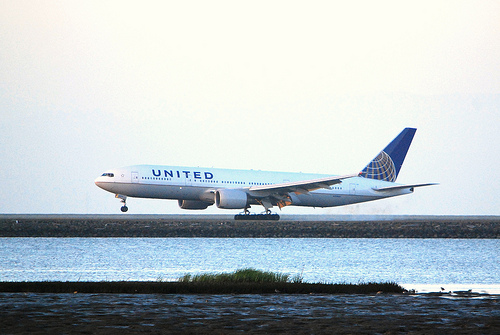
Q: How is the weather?
A: It is clear.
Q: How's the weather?
A: It is clear.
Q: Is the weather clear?
A: Yes, it is clear.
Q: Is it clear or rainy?
A: It is clear.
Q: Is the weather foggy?
A: No, it is clear.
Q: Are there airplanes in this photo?
A: Yes, there is an airplane.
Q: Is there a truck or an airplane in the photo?
A: Yes, there is an airplane.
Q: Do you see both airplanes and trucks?
A: No, there is an airplane but no trucks.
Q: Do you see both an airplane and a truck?
A: No, there is an airplane but no trucks.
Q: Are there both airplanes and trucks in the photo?
A: No, there is an airplane but no trucks.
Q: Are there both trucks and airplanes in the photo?
A: No, there is an airplane but no trucks.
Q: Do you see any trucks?
A: No, there are no trucks.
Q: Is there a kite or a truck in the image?
A: No, there are no trucks or kites.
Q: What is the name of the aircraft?
A: The aircraft is an airplane.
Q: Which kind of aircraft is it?
A: The aircraft is an airplane.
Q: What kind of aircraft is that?
A: This is an airplane.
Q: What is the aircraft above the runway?
A: The aircraft is an airplane.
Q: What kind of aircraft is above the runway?
A: The aircraft is an airplane.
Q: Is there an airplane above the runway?
A: Yes, there is an airplane above the runway.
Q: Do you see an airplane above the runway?
A: Yes, there is an airplane above the runway.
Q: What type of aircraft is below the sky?
A: The aircraft is an airplane.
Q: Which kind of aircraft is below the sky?
A: The aircraft is an airplane.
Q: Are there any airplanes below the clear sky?
A: Yes, there is an airplane below the sky.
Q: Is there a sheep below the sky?
A: No, there is an airplane below the sky.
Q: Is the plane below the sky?
A: Yes, the plane is below the sky.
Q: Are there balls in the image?
A: No, there are no balls.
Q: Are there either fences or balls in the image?
A: No, there are no balls or fences.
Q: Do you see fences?
A: No, there are no fences.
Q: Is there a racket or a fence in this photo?
A: No, there are no fences or rackets.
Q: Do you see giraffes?
A: No, there are no giraffes.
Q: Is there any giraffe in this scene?
A: No, there are no giraffes.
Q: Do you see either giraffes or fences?
A: No, there are no giraffes or fences.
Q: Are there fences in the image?
A: No, there are no fences.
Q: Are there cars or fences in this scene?
A: No, there are no fences or cars.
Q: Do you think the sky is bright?
A: Yes, the sky is bright.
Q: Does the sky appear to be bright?
A: Yes, the sky is bright.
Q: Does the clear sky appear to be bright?
A: Yes, the sky is bright.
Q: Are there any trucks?
A: No, there are no trucks.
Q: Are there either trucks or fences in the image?
A: No, there are no trucks or fences.